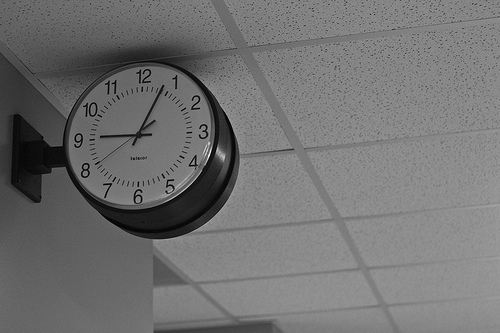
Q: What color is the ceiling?
A: White.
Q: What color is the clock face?
A: White.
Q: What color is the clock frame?
A: Black.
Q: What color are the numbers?
A: Black.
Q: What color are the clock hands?
A: Black.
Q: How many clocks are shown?
A: 1.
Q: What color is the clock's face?
A: White.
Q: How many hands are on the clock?
A: 3.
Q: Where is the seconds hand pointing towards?
A: 8.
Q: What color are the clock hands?
A: Black.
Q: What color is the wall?
A: White.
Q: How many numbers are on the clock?
A: 12.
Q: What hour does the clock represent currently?
A: 9.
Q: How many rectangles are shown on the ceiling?
A: 13.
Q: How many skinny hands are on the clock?
A: 1.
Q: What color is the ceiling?
A: White.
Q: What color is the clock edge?
A: Black.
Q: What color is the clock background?
A: White.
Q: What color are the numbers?
A: Black.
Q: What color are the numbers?
A: Black.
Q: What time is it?
A: 9:04.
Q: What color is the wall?
A: White.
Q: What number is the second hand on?
A: The 8.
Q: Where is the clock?
A: Connected to the wall.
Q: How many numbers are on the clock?
A: 12.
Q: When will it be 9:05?
A: In one minute.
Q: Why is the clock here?
A: To tell time.